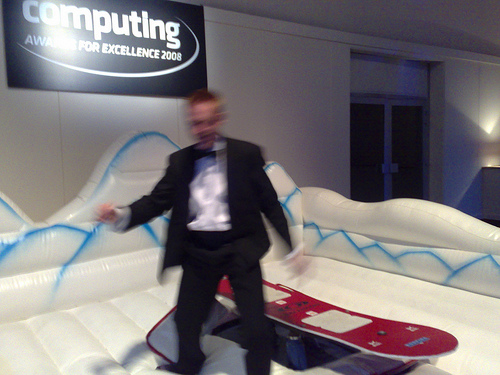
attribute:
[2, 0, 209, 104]
sign — black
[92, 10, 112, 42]
letter — white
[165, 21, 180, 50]
letter — white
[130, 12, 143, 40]
letter — white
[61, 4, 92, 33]
letter — white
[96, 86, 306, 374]
man — standing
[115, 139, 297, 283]
jacket — black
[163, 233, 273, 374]
pants — black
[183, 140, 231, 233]
shirt — white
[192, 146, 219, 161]
tie — black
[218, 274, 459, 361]
snowboard — white, red, fake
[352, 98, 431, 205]
door — double, glass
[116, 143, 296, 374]
tux — black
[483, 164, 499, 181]
light — on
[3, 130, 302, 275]
mountain — fake, blue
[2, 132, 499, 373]
inflatable — white, bouncy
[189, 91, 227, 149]
face — blurry